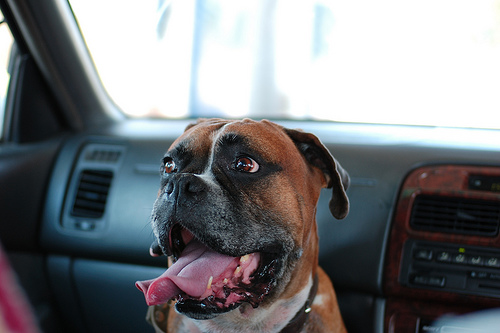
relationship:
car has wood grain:
[103, 72, 494, 271] [422, 171, 455, 204]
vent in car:
[78, 161, 123, 226] [103, 72, 494, 271]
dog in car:
[136, 102, 259, 332] [103, 72, 494, 271]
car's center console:
[360, 282, 444, 330] [426, 164, 497, 327]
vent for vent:
[78, 161, 123, 226] [406, 193, 496, 238]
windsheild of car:
[123, 16, 487, 123] [103, 72, 494, 271]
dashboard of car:
[145, 108, 469, 165] [103, 72, 494, 271]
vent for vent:
[427, 193, 492, 235] [406, 193, 496, 238]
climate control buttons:
[424, 254, 500, 271] [446, 248, 449, 264]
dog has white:
[136, 102, 259, 332] [239, 304, 300, 330]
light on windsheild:
[134, 27, 196, 73] [123, 16, 487, 123]